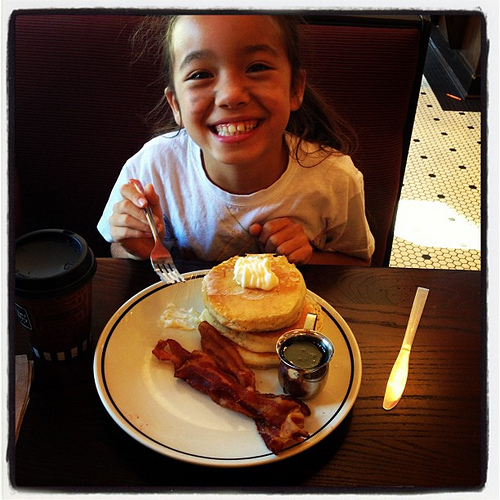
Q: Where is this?
A: A restaurant.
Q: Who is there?
A: A girl.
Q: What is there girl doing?
A: Smiling.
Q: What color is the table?
A: Brown.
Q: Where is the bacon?
A: On the plate.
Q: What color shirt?
A: White.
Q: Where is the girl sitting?
A: In a booth.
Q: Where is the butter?
A: On the pancakes.